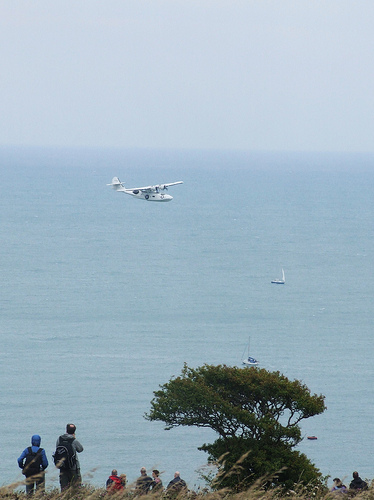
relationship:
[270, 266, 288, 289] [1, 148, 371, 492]
sailboat in water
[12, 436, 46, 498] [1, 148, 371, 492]
person looking at water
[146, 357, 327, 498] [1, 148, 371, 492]
tree in front of water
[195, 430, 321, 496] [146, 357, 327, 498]
bush next to tree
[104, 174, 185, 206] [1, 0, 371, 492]
plane in air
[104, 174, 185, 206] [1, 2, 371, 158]
plane in sky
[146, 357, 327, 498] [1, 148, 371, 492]
tree near water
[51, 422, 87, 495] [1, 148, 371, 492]
person looking at water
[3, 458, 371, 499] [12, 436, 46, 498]
grass near person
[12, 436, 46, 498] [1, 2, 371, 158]
person staring at sky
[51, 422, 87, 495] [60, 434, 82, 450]
person wearing gray shirt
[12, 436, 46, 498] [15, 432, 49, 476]
person wearing blue shirt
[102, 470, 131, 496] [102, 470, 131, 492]
person wearing red shirt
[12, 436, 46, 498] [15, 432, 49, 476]
person wearing hoodie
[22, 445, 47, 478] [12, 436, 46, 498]
backpack on person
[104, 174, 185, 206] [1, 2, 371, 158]
plane flying in sky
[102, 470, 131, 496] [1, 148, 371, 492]
person looking at water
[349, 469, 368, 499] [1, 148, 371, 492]
person looking at water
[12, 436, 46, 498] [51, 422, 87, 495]
person next to person